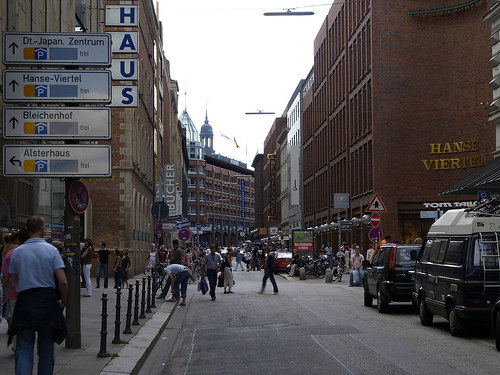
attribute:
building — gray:
[197, 151, 259, 238]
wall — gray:
[353, 0, 495, 230]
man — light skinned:
[0, 220, 70, 374]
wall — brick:
[374, 43, 498, 138]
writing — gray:
[418, 135, 486, 172]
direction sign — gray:
[3, 32, 110, 65]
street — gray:
[135, 260, 495, 372]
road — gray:
[145, 254, 497, 371]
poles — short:
[99, 274, 175, 356]